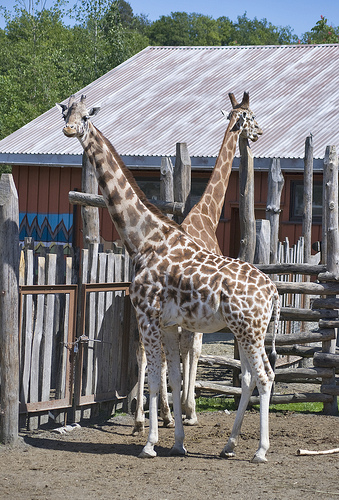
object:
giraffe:
[54, 94, 282, 464]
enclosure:
[0, 236, 339, 498]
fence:
[0, 234, 339, 437]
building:
[0, 44, 338, 287]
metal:
[0, 44, 338, 166]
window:
[289, 177, 323, 225]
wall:
[10, 165, 339, 261]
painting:
[19, 211, 74, 243]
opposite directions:
[55, 91, 263, 142]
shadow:
[23, 424, 253, 463]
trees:
[0, 0, 76, 146]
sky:
[0, 0, 338, 48]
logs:
[1, 172, 24, 446]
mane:
[93, 121, 188, 237]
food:
[269, 399, 325, 413]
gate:
[15, 280, 131, 414]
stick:
[296, 443, 338, 460]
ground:
[0, 330, 339, 500]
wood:
[301, 134, 314, 264]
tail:
[267, 286, 280, 372]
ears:
[87, 106, 101, 118]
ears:
[219, 108, 229, 117]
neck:
[81, 123, 160, 257]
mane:
[196, 115, 234, 209]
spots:
[199, 264, 218, 277]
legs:
[138, 318, 163, 458]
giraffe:
[134, 90, 264, 429]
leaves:
[16, 48, 49, 89]